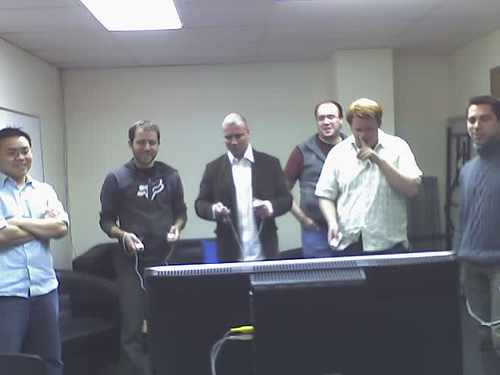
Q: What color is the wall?
A: White.